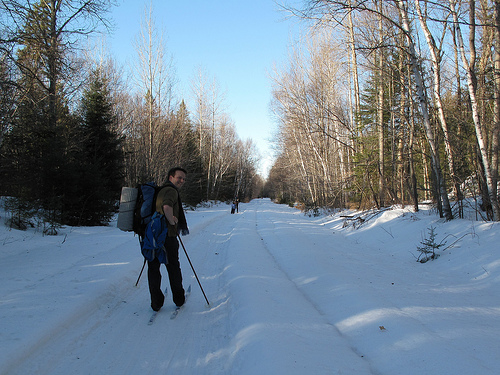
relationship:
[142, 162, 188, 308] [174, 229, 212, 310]
person holding pole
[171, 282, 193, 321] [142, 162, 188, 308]
ski on person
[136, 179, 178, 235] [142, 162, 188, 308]
backpack on person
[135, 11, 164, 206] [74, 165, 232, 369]
tree by snowy trail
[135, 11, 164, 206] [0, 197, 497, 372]
tree by ground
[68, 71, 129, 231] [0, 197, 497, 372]
evergreen by ground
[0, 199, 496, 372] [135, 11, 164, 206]
ground with snowy tree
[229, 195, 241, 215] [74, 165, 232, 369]
man on trail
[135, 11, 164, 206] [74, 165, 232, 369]
tree by trail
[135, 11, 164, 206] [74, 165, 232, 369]
tree on trail